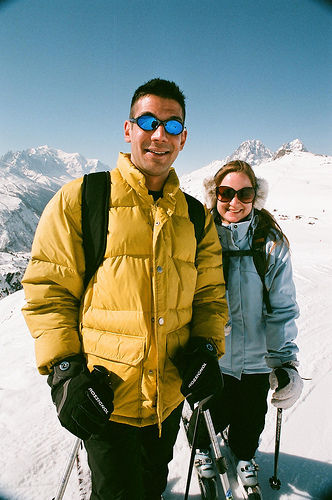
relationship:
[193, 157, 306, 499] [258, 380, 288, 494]
girl has ski poles